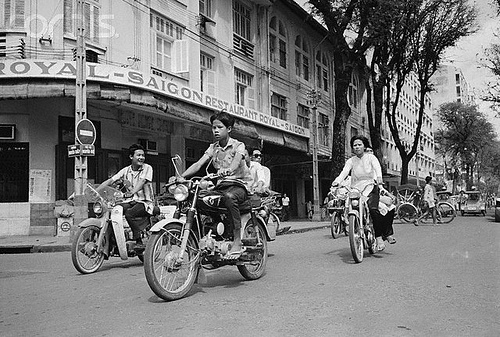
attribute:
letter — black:
[9, 59, 30, 75]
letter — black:
[33, 59, 56, 79]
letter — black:
[57, 60, 75, 78]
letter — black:
[87, 62, 110, 83]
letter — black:
[124, 68, 148, 86]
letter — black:
[144, 73, 160, 89]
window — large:
[145, 5, 197, 88]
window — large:
[199, 47, 222, 100]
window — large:
[233, 63, 257, 108]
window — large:
[269, 85, 291, 122]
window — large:
[292, 100, 313, 131]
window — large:
[314, 106, 336, 146]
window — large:
[312, 46, 335, 92]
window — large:
[266, 9, 289, 68]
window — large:
[216, 28, 263, 68]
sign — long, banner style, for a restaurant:
[14, 56, 323, 142]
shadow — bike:
[133, 290, 178, 315]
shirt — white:
[337, 150, 374, 202]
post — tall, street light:
[61, 40, 91, 251]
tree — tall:
[304, 32, 434, 201]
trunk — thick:
[329, 77, 366, 184]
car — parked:
[456, 179, 498, 223]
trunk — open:
[445, 178, 485, 229]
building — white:
[386, 82, 452, 164]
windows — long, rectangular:
[429, 81, 440, 113]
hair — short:
[189, 92, 270, 156]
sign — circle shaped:
[75, 118, 106, 145]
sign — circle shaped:
[61, 117, 112, 165]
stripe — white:
[64, 122, 94, 139]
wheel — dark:
[137, 214, 214, 299]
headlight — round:
[165, 173, 191, 210]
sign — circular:
[74, 112, 101, 150]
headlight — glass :
[168, 179, 191, 202]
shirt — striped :
[99, 164, 155, 196]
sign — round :
[72, 117, 97, 142]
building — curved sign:
[1, 1, 442, 234]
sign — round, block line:
[65, 117, 105, 145]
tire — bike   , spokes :
[150, 224, 198, 292]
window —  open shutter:
[233, 68, 263, 108]